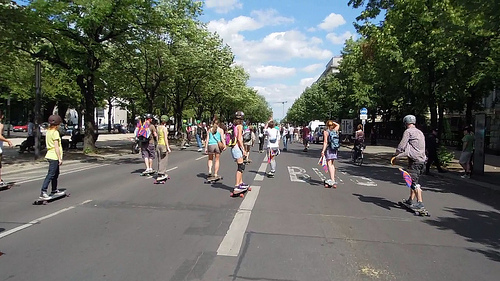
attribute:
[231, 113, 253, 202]
person — skateboarding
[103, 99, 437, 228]
road — gray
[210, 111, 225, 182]
person — skateboarding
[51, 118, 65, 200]
person — skateboarding, young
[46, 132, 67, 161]
shirt — yellow, green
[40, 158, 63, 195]
jeans — black, blue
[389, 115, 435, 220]
person — man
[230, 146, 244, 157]
shorts — blue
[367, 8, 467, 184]
tree — green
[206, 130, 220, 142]
shirt — blue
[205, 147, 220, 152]
shorts — brown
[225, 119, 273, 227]
line — white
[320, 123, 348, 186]
person — skateboarding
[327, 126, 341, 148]
backpack — blue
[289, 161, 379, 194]
word — large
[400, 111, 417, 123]
helmet — gray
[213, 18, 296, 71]
clouds — white, soft, fluffy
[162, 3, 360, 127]
sky — light blue, blue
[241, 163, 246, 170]
pads — black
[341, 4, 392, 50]
sun — out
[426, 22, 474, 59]
leaves — green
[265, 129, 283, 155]
shirt — white